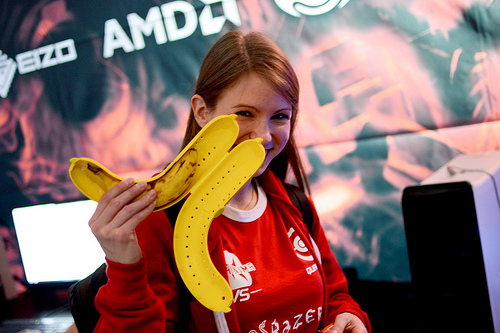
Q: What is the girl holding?
A: A banana case.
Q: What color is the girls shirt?
A: Her shirt is red.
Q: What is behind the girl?
A: A printed mural.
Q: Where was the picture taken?
A: At an event.